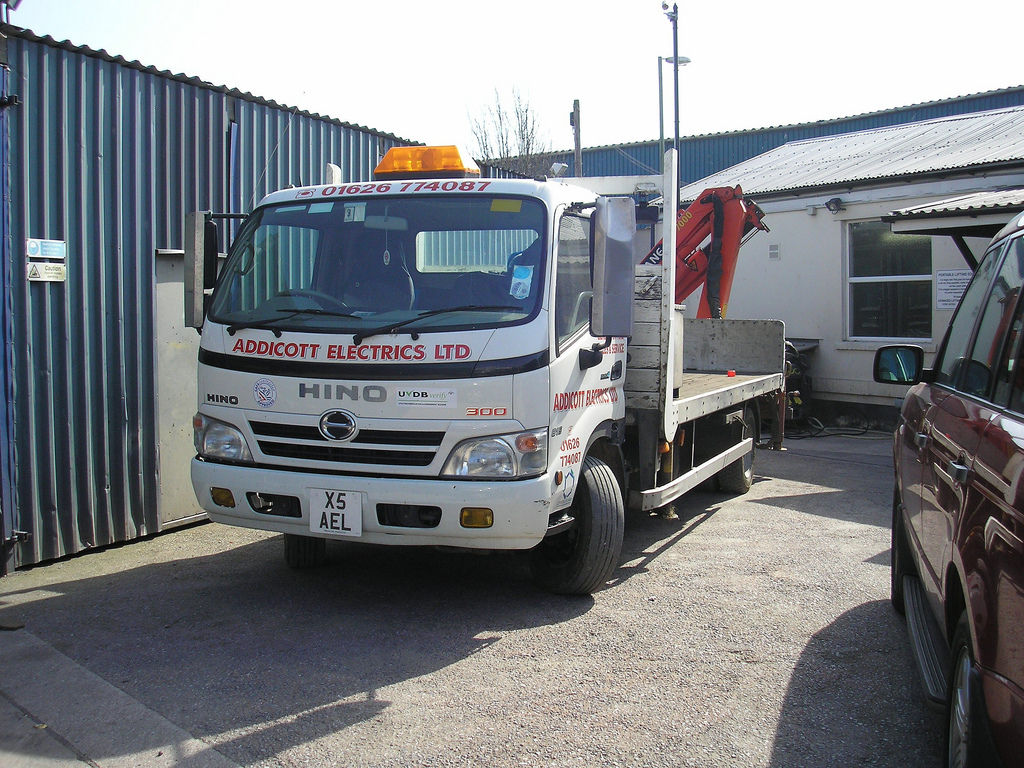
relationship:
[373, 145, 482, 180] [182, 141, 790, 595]
light on top of truck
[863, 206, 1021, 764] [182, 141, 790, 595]
truck parked near truck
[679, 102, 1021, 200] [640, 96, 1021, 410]
metal roof on top of building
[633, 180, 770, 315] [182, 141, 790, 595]
tractor arm behind truck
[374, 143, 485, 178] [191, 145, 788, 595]
light on truck